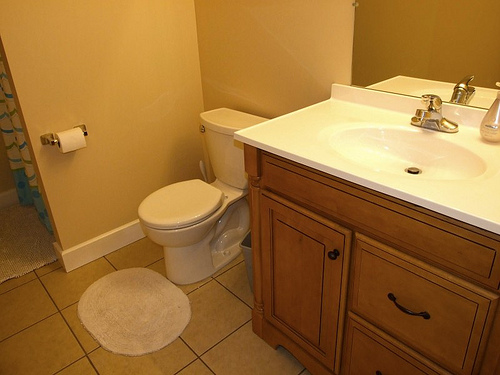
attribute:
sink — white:
[265, 60, 499, 230]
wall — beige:
[2, 0, 353, 256]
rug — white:
[75, 266, 190, 356]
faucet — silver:
[407, 86, 461, 136]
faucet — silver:
[411, 94, 458, 133]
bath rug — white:
[81, 266, 193, 358]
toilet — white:
[152, 118, 310, 296]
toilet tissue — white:
[57, 125, 85, 158]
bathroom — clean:
[0, 2, 496, 372]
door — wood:
[239, 178, 359, 366]